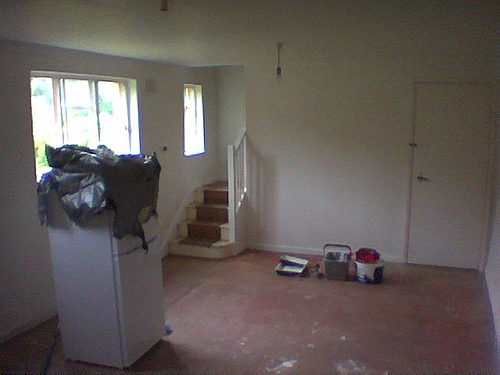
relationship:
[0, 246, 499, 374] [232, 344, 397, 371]
floor with paint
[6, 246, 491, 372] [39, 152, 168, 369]
floor has fridge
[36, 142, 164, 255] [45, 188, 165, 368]
plasic on top of fridge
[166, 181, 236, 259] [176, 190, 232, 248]
steps has brown rug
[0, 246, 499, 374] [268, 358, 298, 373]
floor has powder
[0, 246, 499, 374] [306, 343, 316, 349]
floor has powder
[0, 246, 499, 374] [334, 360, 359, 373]
floor has powder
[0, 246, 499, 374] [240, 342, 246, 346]
floor has powder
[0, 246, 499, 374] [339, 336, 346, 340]
floor has powder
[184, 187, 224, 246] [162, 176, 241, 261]
brown rug on steps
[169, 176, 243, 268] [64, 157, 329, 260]
steps in room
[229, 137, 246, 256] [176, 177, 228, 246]
rail on steps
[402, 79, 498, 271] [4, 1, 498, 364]
door in room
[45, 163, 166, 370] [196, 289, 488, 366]
fridge on floor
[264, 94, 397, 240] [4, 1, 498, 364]
wall in room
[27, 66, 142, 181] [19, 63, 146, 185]
frame on window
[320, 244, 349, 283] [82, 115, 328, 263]
pail in room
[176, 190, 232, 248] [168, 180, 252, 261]
brown rug down center staircase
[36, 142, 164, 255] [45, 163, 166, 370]
plasic covering fridge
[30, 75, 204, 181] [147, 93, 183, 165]
windows on wall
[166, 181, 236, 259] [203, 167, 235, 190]
steps leading to next floor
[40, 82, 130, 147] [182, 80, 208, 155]
sun on window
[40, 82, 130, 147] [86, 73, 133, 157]
sun on window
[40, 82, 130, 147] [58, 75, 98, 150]
sun on window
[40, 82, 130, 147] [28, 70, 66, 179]
sun on window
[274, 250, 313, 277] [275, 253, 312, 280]
brush on paint tray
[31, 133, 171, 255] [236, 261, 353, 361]
plasic above floor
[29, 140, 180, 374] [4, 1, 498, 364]
fridge in room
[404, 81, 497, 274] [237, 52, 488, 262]
door in wall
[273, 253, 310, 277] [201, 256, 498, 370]
paint tray on floor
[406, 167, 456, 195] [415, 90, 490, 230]
door knob on door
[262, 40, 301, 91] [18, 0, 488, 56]
light hanging from ceiling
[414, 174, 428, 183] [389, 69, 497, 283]
door knob on door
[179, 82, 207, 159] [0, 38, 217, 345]
window on wall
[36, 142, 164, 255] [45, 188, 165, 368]
plasic on fridge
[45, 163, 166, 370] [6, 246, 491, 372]
fridge on floor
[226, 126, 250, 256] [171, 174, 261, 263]
rail for stairs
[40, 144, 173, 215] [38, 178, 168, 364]
cover on fridge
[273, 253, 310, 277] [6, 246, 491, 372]
paint tray on floor